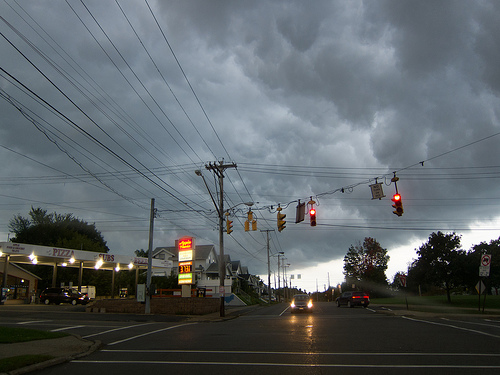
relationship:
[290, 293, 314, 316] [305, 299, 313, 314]
car has headlignt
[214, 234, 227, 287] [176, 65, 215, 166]
pole supporting wires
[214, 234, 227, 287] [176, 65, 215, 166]
pole has wires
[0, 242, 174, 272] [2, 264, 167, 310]
canopy over gas station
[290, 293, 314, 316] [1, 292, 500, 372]
car on road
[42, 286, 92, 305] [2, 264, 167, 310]
car in gas station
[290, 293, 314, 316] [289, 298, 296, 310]
car has light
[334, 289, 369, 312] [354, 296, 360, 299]
car has light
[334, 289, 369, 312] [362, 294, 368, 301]
car has light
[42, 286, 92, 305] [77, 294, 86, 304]
car has light